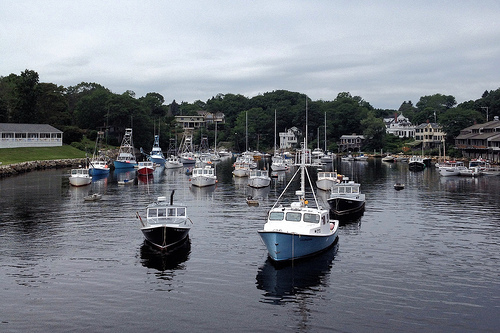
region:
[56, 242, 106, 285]
calm waters of a river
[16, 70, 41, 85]
green leaves of a tree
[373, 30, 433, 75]
white clouds in the sky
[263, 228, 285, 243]
the bow part of a boat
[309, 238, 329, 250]
the body of a boat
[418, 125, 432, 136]
a storey house in the background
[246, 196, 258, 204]
a small boat in the river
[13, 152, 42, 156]
green grass near the river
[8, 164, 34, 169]
a concrete wall along the river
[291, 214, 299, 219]
the glass window of a boat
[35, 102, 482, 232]
several boats in the water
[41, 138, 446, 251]
several boats floating in the water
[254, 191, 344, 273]
a blue and white boat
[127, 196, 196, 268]
a small black boat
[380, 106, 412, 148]
a large white house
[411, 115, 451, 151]
a large tan house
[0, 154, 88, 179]
a rock bank around the water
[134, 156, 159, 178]
a red and white boat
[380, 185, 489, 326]
a body of water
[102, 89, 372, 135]
a row of trees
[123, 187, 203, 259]
the black boat on the water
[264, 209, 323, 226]
the front windows on the boat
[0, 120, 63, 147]
the white building near the water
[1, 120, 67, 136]
the grey roof of the patio area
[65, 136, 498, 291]
the boats parked in the harbor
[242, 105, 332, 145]
the poles for the sails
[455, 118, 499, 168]
the building along the water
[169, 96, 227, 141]
the home in the large trees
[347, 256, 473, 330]
the ripples in the water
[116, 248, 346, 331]
the shado of the boats in the water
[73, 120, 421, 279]
boats in the water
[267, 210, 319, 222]
front windows on a boat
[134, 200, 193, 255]
a black and grey boat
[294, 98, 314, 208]
a mast on a boat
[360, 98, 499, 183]
buildings beside the water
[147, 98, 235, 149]
a building in a wooded area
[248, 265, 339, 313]
a reflection on the water's surface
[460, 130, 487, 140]
the roof of a building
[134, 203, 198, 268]
small boat floating in water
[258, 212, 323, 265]
small boat floating in water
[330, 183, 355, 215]
small boat floating in water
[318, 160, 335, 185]
small boat floating in water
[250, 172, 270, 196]
small boat floating in water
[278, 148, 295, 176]
small boat floating in water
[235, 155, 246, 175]
small boat floating in water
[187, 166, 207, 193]
small boat floating in water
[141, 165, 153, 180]
small boat floating in water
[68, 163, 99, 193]
small boat floating in water